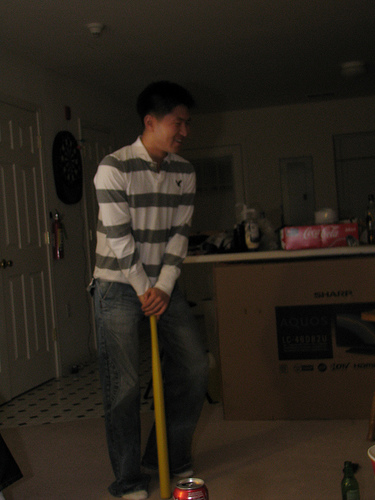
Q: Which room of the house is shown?
A: It is a kitchen.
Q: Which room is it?
A: It is a kitchen.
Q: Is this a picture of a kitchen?
A: Yes, it is showing a kitchen.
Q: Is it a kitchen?
A: Yes, it is a kitchen.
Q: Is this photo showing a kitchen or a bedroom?
A: It is showing a kitchen.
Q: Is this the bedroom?
A: No, it is the kitchen.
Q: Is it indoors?
A: Yes, it is indoors.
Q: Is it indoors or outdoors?
A: It is indoors.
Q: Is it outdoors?
A: No, it is indoors.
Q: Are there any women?
A: No, there are no women.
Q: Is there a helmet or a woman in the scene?
A: No, there are no women or helmets.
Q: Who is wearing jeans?
A: The man is wearing jeans.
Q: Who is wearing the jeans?
A: The man is wearing jeans.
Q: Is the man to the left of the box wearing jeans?
A: Yes, the man is wearing jeans.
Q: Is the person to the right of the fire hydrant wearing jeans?
A: Yes, the man is wearing jeans.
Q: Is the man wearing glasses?
A: No, the man is wearing jeans.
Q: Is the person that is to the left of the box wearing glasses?
A: No, the man is wearing jeans.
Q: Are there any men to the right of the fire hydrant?
A: Yes, there is a man to the right of the fire hydrant.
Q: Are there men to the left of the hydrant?
A: No, the man is to the right of the hydrant.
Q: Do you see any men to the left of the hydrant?
A: No, the man is to the right of the hydrant.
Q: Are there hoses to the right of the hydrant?
A: No, there is a man to the right of the hydrant.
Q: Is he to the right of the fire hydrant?
A: Yes, the man is to the right of the fire hydrant.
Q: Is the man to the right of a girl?
A: No, the man is to the right of the fire hydrant.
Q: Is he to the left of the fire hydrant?
A: No, the man is to the right of the fire hydrant.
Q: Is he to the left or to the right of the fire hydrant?
A: The man is to the right of the fire hydrant.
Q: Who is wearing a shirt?
A: The man is wearing a shirt.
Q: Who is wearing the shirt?
A: The man is wearing a shirt.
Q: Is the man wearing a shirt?
A: Yes, the man is wearing a shirt.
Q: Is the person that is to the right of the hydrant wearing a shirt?
A: Yes, the man is wearing a shirt.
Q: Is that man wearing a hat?
A: No, the man is wearing a shirt.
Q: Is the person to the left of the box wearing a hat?
A: No, the man is wearing a shirt.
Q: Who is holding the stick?
A: The man is holding the stick.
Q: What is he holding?
A: The man is holding the stick.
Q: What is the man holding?
A: The man is holding the stick.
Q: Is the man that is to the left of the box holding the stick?
A: Yes, the man is holding the stick.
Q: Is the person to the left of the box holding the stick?
A: Yes, the man is holding the stick.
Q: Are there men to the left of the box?
A: Yes, there is a man to the left of the box.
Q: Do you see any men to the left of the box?
A: Yes, there is a man to the left of the box.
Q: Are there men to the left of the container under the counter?
A: Yes, there is a man to the left of the box.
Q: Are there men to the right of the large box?
A: No, the man is to the left of the box.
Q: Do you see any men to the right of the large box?
A: No, the man is to the left of the box.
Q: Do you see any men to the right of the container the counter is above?
A: No, the man is to the left of the box.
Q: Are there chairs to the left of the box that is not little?
A: No, there is a man to the left of the box.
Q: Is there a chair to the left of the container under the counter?
A: No, there is a man to the left of the box.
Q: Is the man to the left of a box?
A: Yes, the man is to the left of a box.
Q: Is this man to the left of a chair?
A: No, the man is to the left of a box.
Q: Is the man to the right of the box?
A: No, the man is to the left of the box.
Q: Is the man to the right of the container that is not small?
A: No, the man is to the left of the box.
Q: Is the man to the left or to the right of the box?
A: The man is to the left of the box.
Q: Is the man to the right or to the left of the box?
A: The man is to the left of the box.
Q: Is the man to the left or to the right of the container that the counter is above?
A: The man is to the left of the box.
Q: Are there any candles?
A: No, there are no candles.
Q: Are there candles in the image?
A: No, there are no candles.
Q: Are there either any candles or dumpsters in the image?
A: No, there are no candles or dumpsters.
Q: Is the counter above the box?
A: Yes, the counter is above the box.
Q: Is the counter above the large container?
A: Yes, the counter is above the box.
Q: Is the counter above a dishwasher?
A: No, the counter is above the box.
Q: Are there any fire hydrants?
A: Yes, there is a fire hydrant.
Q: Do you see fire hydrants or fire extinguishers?
A: Yes, there is a fire hydrant.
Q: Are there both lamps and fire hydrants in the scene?
A: No, there is a fire hydrant but no lamps.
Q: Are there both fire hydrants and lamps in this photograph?
A: No, there is a fire hydrant but no lamps.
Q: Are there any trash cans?
A: No, there are no trash cans.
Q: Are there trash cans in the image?
A: No, there are no trash cans.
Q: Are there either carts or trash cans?
A: No, there are no trash cans or carts.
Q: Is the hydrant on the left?
A: Yes, the hydrant is on the left of the image.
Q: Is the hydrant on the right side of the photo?
A: No, the hydrant is on the left of the image.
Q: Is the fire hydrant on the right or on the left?
A: The fire hydrant is on the left of the image.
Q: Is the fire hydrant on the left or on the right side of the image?
A: The fire hydrant is on the left of the image.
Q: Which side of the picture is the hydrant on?
A: The hydrant is on the left of the image.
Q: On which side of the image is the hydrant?
A: The hydrant is on the left of the image.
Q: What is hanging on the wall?
A: The fire hydrant is hanging on the wall.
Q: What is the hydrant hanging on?
A: The hydrant is hanging on the wall.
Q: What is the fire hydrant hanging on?
A: The hydrant is hanging on the wall.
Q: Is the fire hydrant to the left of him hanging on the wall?
A: Yes, the hydrant is hanging on the wall.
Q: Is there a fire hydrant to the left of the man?
A: Yes, there is a fire hydrant to the left of the man.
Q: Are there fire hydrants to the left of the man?
A: Yes, there is a fire hydrant to the left of the man.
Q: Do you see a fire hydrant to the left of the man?
A: Yes, there is a fire hydrant to the left of the man.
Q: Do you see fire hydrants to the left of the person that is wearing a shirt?
A: Yes, there is a fire hydrant to the left of the man.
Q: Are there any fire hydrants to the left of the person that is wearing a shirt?
A: Yes, there is a fire hydrant to the left of the man.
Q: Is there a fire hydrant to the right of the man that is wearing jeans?
A: No, the fire hydrant is to the left of the man.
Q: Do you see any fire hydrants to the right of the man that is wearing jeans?
A: No, the fire hydrant is to the left of the man.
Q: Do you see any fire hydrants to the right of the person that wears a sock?
A: No, the fire hydrant is to the left of the man.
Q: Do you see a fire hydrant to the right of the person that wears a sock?
A: No, the fire hydrant is to the left of the man.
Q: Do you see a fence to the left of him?
A: No, there is a fire hydrant to the left of the man.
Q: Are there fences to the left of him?
A: No, there is a fire hydrant to the left of the man.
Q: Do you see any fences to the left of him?
A: No, there is a fire hydrant to the left of the man.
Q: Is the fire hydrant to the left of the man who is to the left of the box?
A: Yes, the fire hydrant is to the left of the man.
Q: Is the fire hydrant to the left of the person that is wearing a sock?
A: Yes, the fire hydrant is to the left of the man.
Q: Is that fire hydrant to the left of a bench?
A: No, the fire hydrant is to the left of the man.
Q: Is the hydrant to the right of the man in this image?
A: No, the hydrant is to the left of the man.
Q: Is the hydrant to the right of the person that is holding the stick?
A: No, the hydrant is to the left of the man.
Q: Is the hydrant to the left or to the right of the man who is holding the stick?
A: The hydrant is to the left of the man.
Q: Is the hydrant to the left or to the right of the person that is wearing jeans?
A: The hydrant is to the left of the man.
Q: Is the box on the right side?
A: Yes, the box is on the right of the image.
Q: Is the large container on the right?
A: Yes, the box is on the right of the image.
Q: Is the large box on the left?
A: No, the box is on the right of the image.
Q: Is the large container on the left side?
A: No, the box is on the right of the image.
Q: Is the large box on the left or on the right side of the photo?
A: The box is on the right of the image.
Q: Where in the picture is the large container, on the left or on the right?
A: The box is on the right of the image.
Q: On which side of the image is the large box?
A: The box is on the right of the image.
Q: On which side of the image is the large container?
A: The box is on the right of the image.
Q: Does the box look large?
A: Yes, the box is large.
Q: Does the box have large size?
A: Yes, the box is large.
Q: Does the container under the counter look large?
A: Yes, the box is large.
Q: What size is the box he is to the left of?
A: The box is large.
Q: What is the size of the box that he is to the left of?
A: The box is large.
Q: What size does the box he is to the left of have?
A: The box has large size.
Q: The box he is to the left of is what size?
A: The box is large.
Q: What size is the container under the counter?
A: The box is large.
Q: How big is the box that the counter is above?
A: The box is large.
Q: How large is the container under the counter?
A: The box is large.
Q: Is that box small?
A: No, the box is large.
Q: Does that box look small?
A: No, the box is large.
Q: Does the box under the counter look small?
A: No, the box is large.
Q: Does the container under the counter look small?
A: No, the box is large.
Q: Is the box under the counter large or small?
A: The box is large.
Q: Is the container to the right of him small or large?
A: The box is large.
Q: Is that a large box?
A: Yes, that is a large box.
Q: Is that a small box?
A: No, that is a large box.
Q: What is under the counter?
A: The box is under the counter.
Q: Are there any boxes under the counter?
A: Yes, there is a box under the counter.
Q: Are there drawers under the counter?
A: No, there is a box under the counter.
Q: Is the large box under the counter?
A: Yes, the box is under the counter.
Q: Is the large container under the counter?
A: Yes, the box is under the counter.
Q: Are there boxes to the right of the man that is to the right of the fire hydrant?
A: Yes, there is a box to the right of the man.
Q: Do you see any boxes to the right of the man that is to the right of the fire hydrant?
A: Yes, there is a box to the right of the man.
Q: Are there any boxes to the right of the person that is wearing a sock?
A: Yes, there is a box to the right of the man.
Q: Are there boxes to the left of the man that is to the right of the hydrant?
A: No, the box is to the right of the man.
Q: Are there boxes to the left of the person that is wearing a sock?
A: No, the box is to the right of the man.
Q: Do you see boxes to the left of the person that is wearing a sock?
A: No, the box is to the right of the man.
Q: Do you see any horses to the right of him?
A: No, there is a box to the right of the man.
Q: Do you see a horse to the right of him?
A: No, there is a box to the right of the man.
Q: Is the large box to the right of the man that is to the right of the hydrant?
A: Yes, the box is to the right of the man.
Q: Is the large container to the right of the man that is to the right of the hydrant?
A: Yes, the box is to the right of the man.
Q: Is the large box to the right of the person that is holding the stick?
A: Yes, the box is to the right of the man.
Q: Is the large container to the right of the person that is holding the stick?
A: Yes, the box is to the right of the man.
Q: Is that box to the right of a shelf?
A: No, the box is to the right of the man.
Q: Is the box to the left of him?
A: No, the box is to the right of the man.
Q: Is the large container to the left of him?
A: No, the box is to the right of the man.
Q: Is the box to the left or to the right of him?
A: The box is to the right of the man.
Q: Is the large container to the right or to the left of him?
A: The box is to the right of the man.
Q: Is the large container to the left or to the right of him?
A: The box is to the right of the man.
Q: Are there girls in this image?
A: No, there are no girls.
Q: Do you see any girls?
A: No, there are no girls.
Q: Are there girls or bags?
A: No, there are no girls or bags.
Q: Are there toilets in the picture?
A: No, there are no toilets.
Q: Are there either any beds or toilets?
A: No, there are no toilets or beds.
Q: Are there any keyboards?
A: No, there are no keyboards.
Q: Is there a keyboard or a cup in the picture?
A: No, there are no keyboards or cups.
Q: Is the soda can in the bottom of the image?
A: Yes, the soda can is in the bottom of the image.